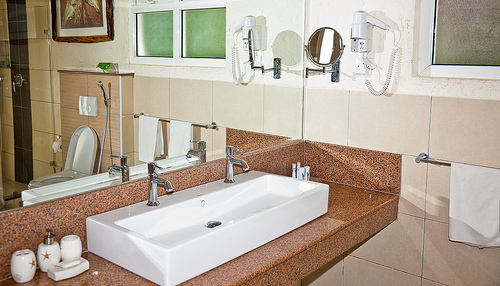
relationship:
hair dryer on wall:
[353, 7, 408, 97] [304, 6, 499, 286]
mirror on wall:
[309, 27, 342, 66] [304, 6, 499, 286]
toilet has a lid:
[29, 124, 99, 189] [62, 124, 98, 176]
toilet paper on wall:
[52, 142, 65, 151] [304, 6, 499, 286]